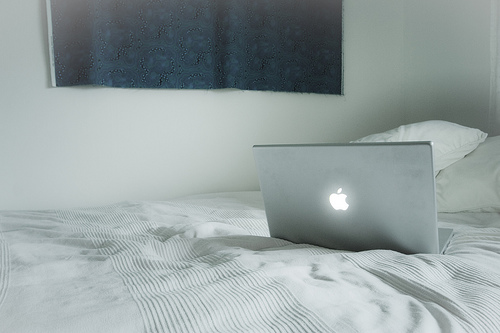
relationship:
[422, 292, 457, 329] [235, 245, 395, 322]
fold in blanket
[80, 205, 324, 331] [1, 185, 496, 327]
lines on spread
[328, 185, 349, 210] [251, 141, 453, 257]
apple in laptop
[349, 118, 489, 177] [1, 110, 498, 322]
pillow in bed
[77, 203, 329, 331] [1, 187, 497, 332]
ridged lines on bedspread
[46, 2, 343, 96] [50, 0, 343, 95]
fabric hanging on window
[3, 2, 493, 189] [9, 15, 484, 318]
walls in bedroom